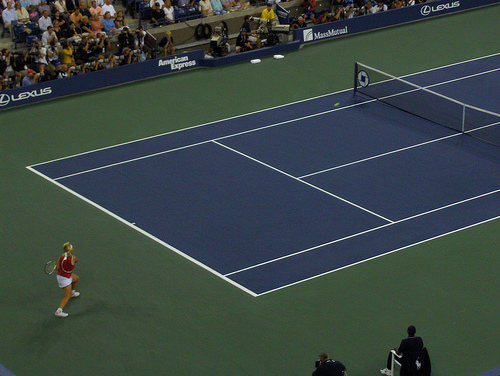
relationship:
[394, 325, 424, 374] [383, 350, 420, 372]
man sitting on chair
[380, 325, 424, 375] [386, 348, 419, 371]
man sitting on chair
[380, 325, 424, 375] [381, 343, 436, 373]
man sitting on chair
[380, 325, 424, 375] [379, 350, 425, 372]
man sitting on chair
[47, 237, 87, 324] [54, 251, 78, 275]
woman wearing shirt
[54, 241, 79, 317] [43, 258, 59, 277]
lady holding racket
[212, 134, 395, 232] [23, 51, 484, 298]
line on court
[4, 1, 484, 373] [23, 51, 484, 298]
trim around court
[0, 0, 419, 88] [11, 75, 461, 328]
person watching match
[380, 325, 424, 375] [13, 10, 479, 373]
man sitting on court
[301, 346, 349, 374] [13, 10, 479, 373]
person sitting on court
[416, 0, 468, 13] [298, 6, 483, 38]
logo on wall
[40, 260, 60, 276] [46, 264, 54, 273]
racket has net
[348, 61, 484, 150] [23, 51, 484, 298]
net on court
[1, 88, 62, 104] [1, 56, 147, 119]
word on wall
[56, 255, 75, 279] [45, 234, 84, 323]
shirt on woman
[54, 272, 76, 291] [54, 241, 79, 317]
skirt on lady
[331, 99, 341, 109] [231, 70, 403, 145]
ball in air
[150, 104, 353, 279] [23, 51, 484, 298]
line painted on court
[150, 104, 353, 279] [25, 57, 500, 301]
line painted on match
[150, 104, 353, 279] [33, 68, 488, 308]
line painted on court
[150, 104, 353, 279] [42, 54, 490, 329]
line painted on tennis court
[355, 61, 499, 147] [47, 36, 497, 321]
net on court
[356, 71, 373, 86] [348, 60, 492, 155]
logo on net